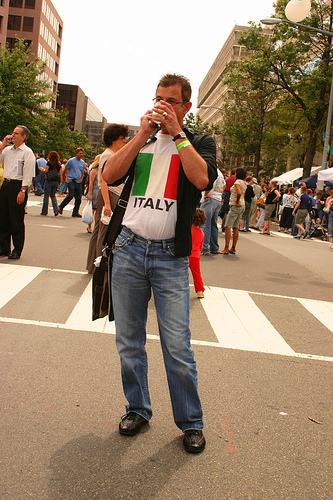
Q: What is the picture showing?
A: It is showing a street.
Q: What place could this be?
A: It is a street.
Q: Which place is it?
A: It is a street.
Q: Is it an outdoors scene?
A: Yes, it is outdoors.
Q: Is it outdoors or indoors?
A: It is outdoors.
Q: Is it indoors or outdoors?
A: It is outdoors.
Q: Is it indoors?
A: No, it is outdoors.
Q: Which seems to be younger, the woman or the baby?
A: The baby is younger than the woman.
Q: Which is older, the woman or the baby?
A: The woman is older than the baby.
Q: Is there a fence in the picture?
A: No, there are no fences.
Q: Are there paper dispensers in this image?
A: No, there are no paper dispensers.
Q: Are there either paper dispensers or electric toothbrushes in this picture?
A: No, there are no paper dispensers or electric toothbrushes.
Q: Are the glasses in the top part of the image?
A: Yes, the glasses are in the top of the image.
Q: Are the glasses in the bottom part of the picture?
A: No, the glasses are in the top of the image.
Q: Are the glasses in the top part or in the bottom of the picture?
A: The glasses are in the top of the image.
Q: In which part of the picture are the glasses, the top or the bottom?
A: The glasses are in the top of the image.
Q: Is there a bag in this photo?
A: Yes, there is a bag.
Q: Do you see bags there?
A: Yes, there is a bag.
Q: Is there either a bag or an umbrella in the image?
A: Yes, there is a bag.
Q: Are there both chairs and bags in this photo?
A: Yes, there are both a bag and a chair.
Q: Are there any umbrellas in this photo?
A: No, there are no umbrellas.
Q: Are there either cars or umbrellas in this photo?
A: No, there are no umbrellas or cars.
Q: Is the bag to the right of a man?
A: Yes, the bag is to the right of a man.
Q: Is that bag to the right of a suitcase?
A: No, the bag is to the right of a man.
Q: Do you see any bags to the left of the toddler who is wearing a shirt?
A: Yes, there is a bag to the left of the toddler.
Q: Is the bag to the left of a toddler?
A: Yes, the bag is to the left of a toddler.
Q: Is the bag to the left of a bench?
A: No, the bag is to the left of a toddler.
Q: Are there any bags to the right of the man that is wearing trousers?
A: Yes, there is a bag to the right of the man.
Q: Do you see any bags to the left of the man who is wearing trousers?
A: No, the bag is to the right of the man.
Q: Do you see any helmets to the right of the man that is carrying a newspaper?
A: No, there is a bag to the right of the man.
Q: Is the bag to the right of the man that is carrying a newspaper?
A: Yes, the bag is to the right of the man.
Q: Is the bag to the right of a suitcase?
A: No, the bag is to the right of the man.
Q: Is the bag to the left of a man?
A: No, the bag is to the right of a man.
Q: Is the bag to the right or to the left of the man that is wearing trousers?
A: The bag is to the right of the man.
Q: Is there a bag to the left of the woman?
A: Yes, there is a bag to the left of the woman.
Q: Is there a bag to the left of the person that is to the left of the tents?
A: Yes, there is a bag to the left of the woman.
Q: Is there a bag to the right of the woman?
A: No, the bag is to the left of the woman.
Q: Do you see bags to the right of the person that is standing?
A: No, the bag is to the left of the woman.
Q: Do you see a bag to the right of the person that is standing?
A: No, the bag is to the left of the woman.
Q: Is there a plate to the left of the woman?
A: No, there is a bag to the left of the woman.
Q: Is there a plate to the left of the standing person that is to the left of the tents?
A: No, there is a bag to the left of the woman.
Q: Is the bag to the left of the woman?
A: Yes, the bag is to the left of the woman.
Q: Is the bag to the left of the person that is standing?
A: Yes, the bag is to the left of the woman.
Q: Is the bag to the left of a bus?
A: No, the bag is to the left of the woman.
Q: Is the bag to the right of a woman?
A: No, the bag is to the left of a woman.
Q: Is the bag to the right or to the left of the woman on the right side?
A: The bag is to the left of the woman.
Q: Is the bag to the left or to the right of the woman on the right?
A: The bag is to the left of the woman.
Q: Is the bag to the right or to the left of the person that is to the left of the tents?
A: The bag is to the left of the woman.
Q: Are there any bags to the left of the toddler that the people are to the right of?
A: Yes, there is a bag to the left of the toddler.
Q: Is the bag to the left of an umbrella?
A: No, the bag is to the left of a toddler.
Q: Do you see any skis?
A: No, there are no skis.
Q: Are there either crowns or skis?
A: No, there are no skis or crowns.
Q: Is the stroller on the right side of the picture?
A: Yes, the stroller is on the right of the image.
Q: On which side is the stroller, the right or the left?
A: The stroller is on the right of the image.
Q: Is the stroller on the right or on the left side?
A: The stroller is on the right of the image.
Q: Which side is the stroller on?
A: The stroller is on the right of the image.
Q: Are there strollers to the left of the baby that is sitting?
A: Yes, there is a stroller to the left of the baby.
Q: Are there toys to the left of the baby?
A: No, there is a stroller to the left of the baby.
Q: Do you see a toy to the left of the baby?
A: No, there is a stroller to the left of the baby.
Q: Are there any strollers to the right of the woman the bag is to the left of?
A: Yes, there is a stroller to the right of the woman.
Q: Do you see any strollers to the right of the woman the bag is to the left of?
A: Yes, there is a stroller to the right of the woman.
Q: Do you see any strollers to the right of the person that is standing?
A: Yes, there is a stroller to the right of the woman.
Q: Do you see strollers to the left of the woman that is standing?
A: No, the stroller is to the right of the woman.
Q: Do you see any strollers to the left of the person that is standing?
A: No, the stroller is to the right of the woman.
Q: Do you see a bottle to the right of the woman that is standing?
A: No, there is a stroller to the right of the woman.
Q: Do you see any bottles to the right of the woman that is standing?
A: No, there is a stroller to the right of the woman.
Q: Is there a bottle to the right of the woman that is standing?
A: No, there is a stroller to the right of the woman.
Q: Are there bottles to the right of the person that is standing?
A: No, there is a stroller to the right of the woman.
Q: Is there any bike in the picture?
A: No, there are no bikes.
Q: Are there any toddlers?
A: Yes, there is a toddler.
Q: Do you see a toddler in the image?
A: Yes, there is a toddler.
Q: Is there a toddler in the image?
A: Yes, there is a toddler.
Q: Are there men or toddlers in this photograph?
A: Yes, there is a toddler.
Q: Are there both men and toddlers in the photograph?
A: Yes, there are both a toddler and a man.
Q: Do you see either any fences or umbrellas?
A: No, there are no fences or umbrellas.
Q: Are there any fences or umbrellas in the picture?
A: No, there are no fences or umbrellas.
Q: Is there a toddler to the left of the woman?
A: Yes, there is a toddler to the left of the woman.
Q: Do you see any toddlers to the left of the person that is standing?
A: Yes, there is a toddler to the left of the woman.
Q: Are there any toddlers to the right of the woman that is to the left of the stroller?
A: No, the toddler is to the left of the woman.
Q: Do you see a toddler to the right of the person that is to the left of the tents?
A: No, the toddler is to the left of the woman.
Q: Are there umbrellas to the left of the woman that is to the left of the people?
A: No, there is a toddler to the left of the woman.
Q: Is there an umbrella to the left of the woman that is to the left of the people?
A: No, there is a toddler to the left of the woman.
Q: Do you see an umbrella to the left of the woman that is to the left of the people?
A: No, there is a toddler to the left of the woman.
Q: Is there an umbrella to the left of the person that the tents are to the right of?
A: No, there is a toddler to the left of the woman.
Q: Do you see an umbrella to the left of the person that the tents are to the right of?
A: No, there is a toddler to the left of the woman.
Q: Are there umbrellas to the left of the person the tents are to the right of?
A: No, there is a toddler to the left of the woman.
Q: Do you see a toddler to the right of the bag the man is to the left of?
A: Yes, there is a toddler to the right of the bag.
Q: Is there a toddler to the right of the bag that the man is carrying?
A: Yes, there is a toddler to the right of the bag.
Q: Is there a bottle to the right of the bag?
A: No, there is a toddler to the right of the bag.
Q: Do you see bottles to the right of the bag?
A: No, there is a toddler to the right of the bag.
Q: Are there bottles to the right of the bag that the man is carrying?
A: No, there is a toddler to the right of the bag.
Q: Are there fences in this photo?
A: No, there are no fences.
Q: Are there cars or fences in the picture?
A: No, there are no fences or cars.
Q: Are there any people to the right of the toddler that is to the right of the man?
A: Yes, there are people to the right of the toddler.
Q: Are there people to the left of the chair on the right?
A: Yes, there are people to the left of the chair.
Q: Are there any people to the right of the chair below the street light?
A: No, the people are to the left of the chair.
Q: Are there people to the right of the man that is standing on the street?
A: Yes, there are people to the right of the man.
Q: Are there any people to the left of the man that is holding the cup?
A: No, the people are to the right of the man.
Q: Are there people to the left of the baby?
A: Yes, there are people to the left of the baby.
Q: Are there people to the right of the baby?
A: No, the people are to the left of the baby.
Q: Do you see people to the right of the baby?
A: No, the people are to the left of the baby.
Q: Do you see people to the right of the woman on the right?
A: Yes, there are people to the right of the woman.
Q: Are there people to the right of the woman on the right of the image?
A: Yes, there are people to the right of the woman.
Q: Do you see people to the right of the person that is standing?
A: Yes, there are people to the right of the woman.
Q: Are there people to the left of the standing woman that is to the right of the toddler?
A: No, the people are to the right of the woman.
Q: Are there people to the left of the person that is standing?
A: No, the people are to the right of the woman.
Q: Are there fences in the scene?
A: No, there are no fences.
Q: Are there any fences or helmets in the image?
A: No, there are no fences or helmets.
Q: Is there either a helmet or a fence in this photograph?
A: No, there are no helmets or fences.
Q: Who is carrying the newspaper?
A: The man is carrying the newspaper.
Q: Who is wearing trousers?
A: The man is wearing trousers.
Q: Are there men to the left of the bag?
A: Yes, there is a man to the left of the bag.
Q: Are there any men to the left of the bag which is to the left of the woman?
A: Yes, there is a man to the left of the bag.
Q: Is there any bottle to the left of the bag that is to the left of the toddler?
A: No, there is a man to the left of the bag.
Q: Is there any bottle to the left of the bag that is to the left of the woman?
A: No, there is a man to the left of the bag.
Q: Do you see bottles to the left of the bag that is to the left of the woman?
A: No, there is a man to the left of the bag.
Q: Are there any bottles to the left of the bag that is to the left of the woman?
A: No, there is a man to the left of the bag.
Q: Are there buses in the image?
A: No, there are no buses.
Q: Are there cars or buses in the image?
A: No, there are no buses or cars.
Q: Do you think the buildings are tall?
A: Yes, the buildings are tall.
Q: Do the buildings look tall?
A: Yes, the buildings are tall.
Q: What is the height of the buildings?
A: The buildings are tall.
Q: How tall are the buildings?
A: The buildings are tall.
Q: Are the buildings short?
A: No, the buildings are tall.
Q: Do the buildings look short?
A: No, the buildings are tall.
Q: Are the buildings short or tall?
A: The buildings are tall.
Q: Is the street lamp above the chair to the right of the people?
A: Yes, the street lamp is above the chair.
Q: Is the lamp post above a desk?
A: No, the lamp post is above the chair.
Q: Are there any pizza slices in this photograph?
A: No, there are no pizza slices.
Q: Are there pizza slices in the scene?
A: No, there are no pizza slices.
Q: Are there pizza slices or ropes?
A: No, there are no pizza slices or ropes.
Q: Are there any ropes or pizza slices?
A: No, there are no pizza slices or ropes.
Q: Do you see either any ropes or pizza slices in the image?
A: No, there are no pizza slices or ropes.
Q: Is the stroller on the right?
A: Yes, the stroller is on the right of the image.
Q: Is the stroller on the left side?
A: No, the stroller is on the right of the image.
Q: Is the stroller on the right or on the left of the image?
A: The stroller is on the right of the image.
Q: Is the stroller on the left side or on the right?
A: The stroller is on the right of the image.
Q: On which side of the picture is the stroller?
A: The stroller is on the right of the image.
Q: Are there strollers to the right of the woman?
A: Yes, there is a stroller to the right of the woman.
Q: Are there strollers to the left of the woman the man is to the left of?
A: No, the stroller is to the right of the woman.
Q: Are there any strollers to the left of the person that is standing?
A: No, the stroller is to the right of the woman.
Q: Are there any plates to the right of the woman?
A: No, there is a stroller to the right of the woman.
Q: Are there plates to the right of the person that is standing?
A: No, there is a stroller to the right of the woman.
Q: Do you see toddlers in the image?
A: Yes, there is a toddler.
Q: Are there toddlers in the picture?
A: Yes, there is a toddler.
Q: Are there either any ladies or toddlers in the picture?
A: Yes, there is a toddler.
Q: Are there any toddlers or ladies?
A: Yes, there is a toddler.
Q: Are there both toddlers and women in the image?
A: Yes, there are both a toddler and a woman.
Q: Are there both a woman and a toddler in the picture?
A: Yes, there are both a toddler and a woman.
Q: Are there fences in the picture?
A: No, there are no fences.